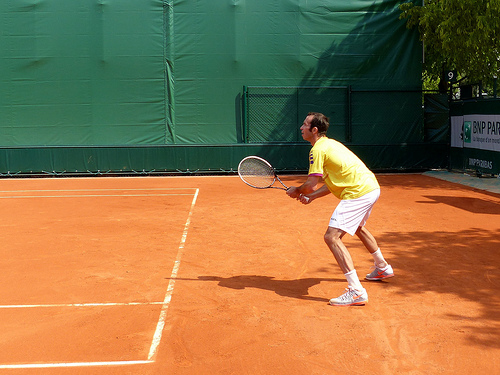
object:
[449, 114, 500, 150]
advertisement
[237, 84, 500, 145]
fence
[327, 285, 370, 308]
shoe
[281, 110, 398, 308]
man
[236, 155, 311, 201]
racket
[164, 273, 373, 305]
shadow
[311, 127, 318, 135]
ear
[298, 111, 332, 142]
head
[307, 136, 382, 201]
shirt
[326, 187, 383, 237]
shorts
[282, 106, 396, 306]
player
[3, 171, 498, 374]
floor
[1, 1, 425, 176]
covering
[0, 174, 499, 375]
court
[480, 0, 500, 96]
trees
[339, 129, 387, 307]
back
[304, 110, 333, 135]
hair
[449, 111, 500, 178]
signs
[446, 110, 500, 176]
walls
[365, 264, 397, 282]
sneaker